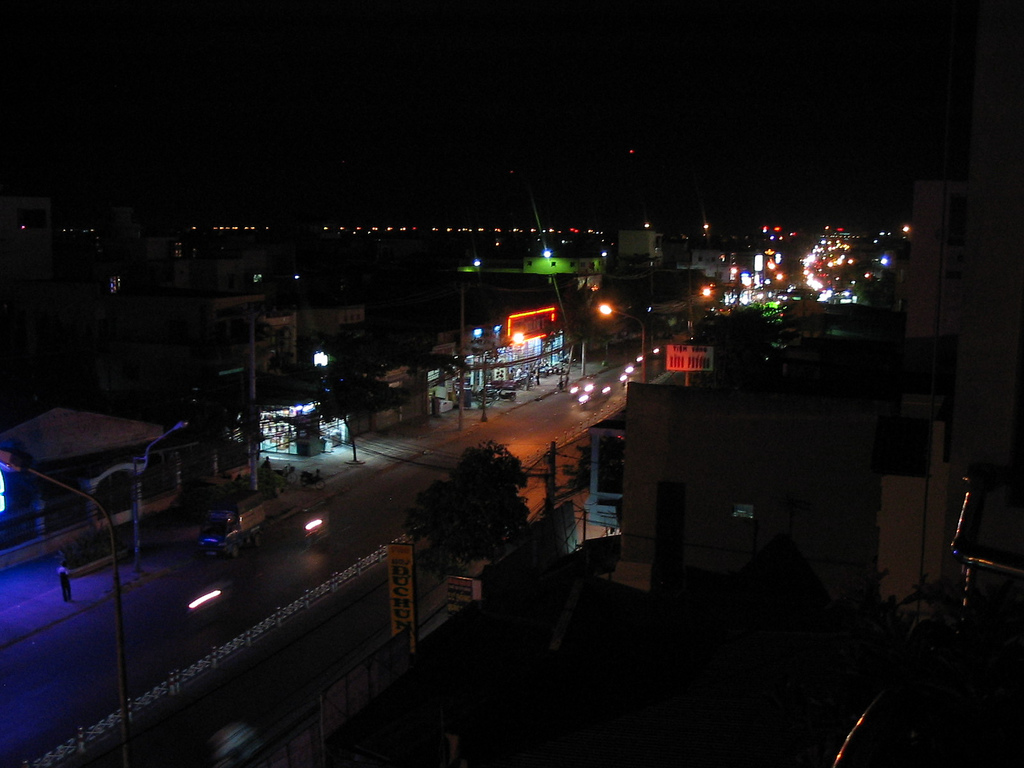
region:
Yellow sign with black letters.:
[379, 539, 421, 653]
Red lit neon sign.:
[508, 301, 566, 347]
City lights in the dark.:
[34, 204, 910, 304]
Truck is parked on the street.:
[201, 478, 285, 571]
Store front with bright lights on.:
[470, 294, 589, 415]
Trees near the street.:
[413, 428, 518, 572]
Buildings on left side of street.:
[8, 229, 748, 549]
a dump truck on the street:
[196, 486, 267, 556]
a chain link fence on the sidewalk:
[251, 627, 419, 765]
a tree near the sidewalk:
[412, 440, 534, 636]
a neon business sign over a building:
[510, 311, 559, 343]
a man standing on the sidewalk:
[55, 561, 78, 606]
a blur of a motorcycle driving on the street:
[185, 586, 227, 635]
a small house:
[21, 410, 170, 546]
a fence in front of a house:
[0, 442, 264, 563]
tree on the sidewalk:
[312, 333, 390, 471]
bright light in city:
[577, 280, 651, 350]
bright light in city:
[464, 289, 548, 392]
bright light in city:
[306, 328, 349, 371]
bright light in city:
[520, 230, 606, 319]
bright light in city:
[707, 254, 764, 315]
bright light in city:
[755, 243, 787, 292]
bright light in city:
[792, 249, 849, 306]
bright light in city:
[792, 226, 866, 297]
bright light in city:
[844, 236, 899, 282]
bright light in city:
[550, 375, 620, 411]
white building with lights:
[444, 302, 584, 416]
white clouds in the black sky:
[176, 145, 262, 209]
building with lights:
[408, 281, 644, 456]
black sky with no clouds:
[196, 16, 286, 118]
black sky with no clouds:
[392, 83, 403, 97]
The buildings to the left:
[69, 274, 749, 531]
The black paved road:
[15, 307, 682, 709]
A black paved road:
[13, 300, 715, 702]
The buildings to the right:
[309, 268, 1002, 762]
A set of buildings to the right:
[280, 274, 1017, 750]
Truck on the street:
[186, 486, 291, 559]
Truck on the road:
[173, 486, 295, 559]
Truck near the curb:
[189, 487, 297, 560]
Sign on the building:
[483, 301, 579, 343]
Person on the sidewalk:
[46, 550, 94, 599]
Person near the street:
[49, 560, 89, 611]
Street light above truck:
[132, 411, 203, 579]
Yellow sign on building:
[367, 531, 424, 656]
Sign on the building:
[644, 334, 733, 373]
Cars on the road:
[544, 345, 637, 416]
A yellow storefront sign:
[381, 535, 427, 666]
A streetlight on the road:
[0, 445, 160, 763]